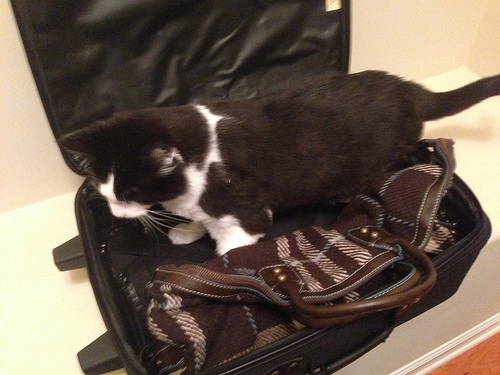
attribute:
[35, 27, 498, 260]
cat — black, white, small, sitting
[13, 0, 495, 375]
suit case — black, open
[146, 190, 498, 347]
purse — brown, white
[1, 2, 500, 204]
wall — white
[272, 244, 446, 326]
handle — brown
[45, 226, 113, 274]
leg — black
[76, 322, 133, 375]
leg — black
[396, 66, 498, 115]
tail — black, long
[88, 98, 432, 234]
hair — short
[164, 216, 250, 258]
paws — furry, white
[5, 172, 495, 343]
table — white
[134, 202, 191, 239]
whiskers — white